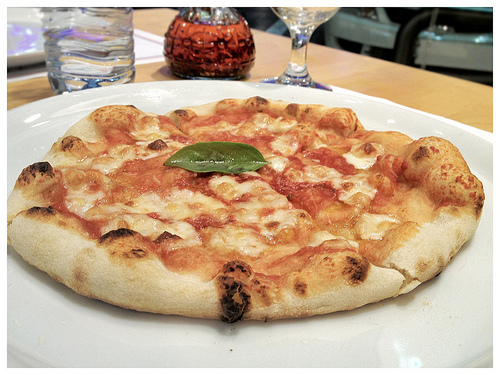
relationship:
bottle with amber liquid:
[161, 8, 261, 82] [165, 21, 256, 72]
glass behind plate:
[259, 5, 340, 92] [37, 84, 487, 361]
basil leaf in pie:
[162, 141, 272, 174] [7, 95, 484, 321]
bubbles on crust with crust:
[402, 135, 484, 204] [18, 240, 490, 320]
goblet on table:
[164, 9, 256, 79] [10, 9, 489, 367]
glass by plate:
[259, 5, 340, 92] [37, 84, 487, 361]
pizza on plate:
[19, 94, 477, 306] [7, 275, 499, 365]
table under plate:
[356, 46, 497, 130] [76, 65, 360, 142]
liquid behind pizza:
[162, 19, 258, 80] [19, 94, 477, 306]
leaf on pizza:
[165, 136, 264, 172] [19, 94, 477, 306]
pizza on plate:
[19, 94, 477, 306] [37, 84, 487, 361]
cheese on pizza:
[53, 109, 413, 266] [19, 94, 477, 306]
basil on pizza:
[158, 136, 273, 189] [19, 94, 477, 306]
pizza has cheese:
[19, 94, 477, 306] [114, 158, 300, 268]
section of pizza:
[84, 164, 260, 324] [19, 94, 477, 306]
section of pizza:
[268, 129, 487, 303] [19, 94, 477, 306]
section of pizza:
[49, 86, 271, 224] [83, 92, 242, 213]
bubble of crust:
[215, 264, 248, 326] [11, 95, 483, 327]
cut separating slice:
[249, 164, 456, 303] [173, 96, 483, 283]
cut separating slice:
[249, 164, 456, 303] [9, 104, 400, 320]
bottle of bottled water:
[245, 7, 422, 92] [35, 5, 146, 90]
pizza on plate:
[19, 94, 477, 306] [6, 80, 494, 374]